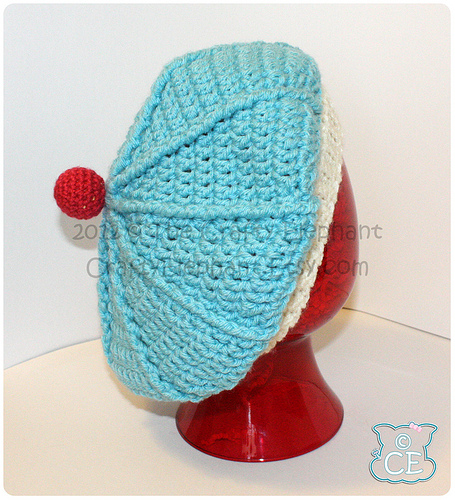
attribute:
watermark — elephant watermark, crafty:
[62, 208, 409, 296]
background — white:
[6, 11, 447, 355]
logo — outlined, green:
[369, 421, 436, 486]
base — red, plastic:
[171, 336, 345, 470]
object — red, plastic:
[185, 150, 389, 467]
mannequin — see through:
[79, 72, 428, 432]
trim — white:
[314, 75, 347, 302]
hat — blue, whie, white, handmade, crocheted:
[50, 28, 347, 408]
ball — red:
[56, 165, 106, 218]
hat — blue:
[40, 38, 400, 416]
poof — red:
[39, 162, 120, 217]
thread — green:
[93, 82, 286, 267]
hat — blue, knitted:
[102, 47, 304, 362]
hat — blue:
[115, 80, 297, 377]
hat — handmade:
[46, 48, 357, 386]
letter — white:
[379, 447, 405, 478]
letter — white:
[402, 449, 425, 478]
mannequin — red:
[172, 150, 362, 468]